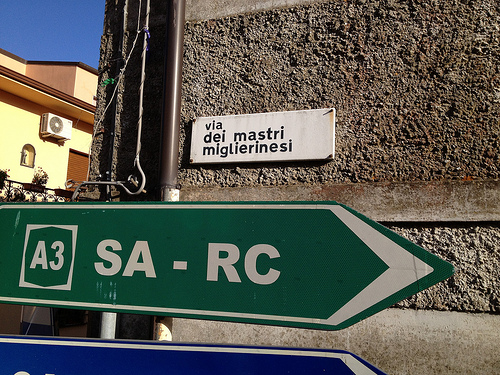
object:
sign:
[0, 201, 454, 332]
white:
[63, 124, 72, 137]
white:
[189, 108, 335, 163]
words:
[233, 126, 283, 141]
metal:
[71, 181, 119, 199]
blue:
[0, 335, 381, 374]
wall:
[92, 0, 497, 375]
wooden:
[69, 149, 88, 178]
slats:
[70, 155, 88, 162]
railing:
[4, 179, 24, 185]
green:
[103, 78, 114, 85]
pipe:
[160, 0, 183, 185]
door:
[68, 149, 90, 190]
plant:
[31, 166, 49, 184]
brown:
[162, 0, 186, 184]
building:
[0, 50, 104, 204]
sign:
[188, 108, 336, 164]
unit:
[40, 113, 72, 142]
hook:
[122, 156, 146, 195]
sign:
[0, 336, 385, 374]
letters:
[204, 132, 212, 143]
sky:
[0, 0, 101, 68]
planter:
[23, 183, 43, 192]